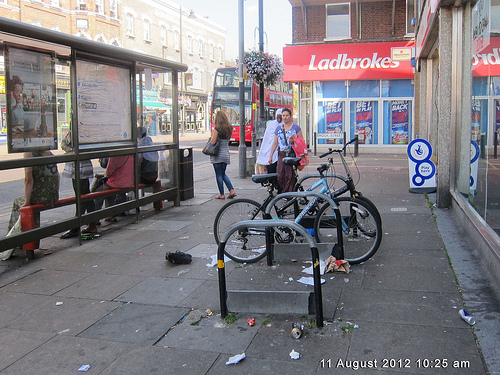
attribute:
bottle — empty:
[456, 307, 483, 335]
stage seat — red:
[18, 177, 164, 257]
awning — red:
[282, 39, 422, 92]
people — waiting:
[268, 106, 298, 180]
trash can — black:
[169, 142, 194, 200]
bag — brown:
[201, 133, 219, 158]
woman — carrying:
[271, 109, 311, 194]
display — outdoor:
[405, 139, 440, 192]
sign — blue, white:
[404, 133, 446, 205]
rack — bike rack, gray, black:
[212, 145, 380, 317]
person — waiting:
[138, 121, 158, 189]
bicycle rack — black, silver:
[217, 188, 354, 335]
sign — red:
[288, 35, 415, 88]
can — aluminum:
[288, 323, 304, 338]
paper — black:
[161, 250, 191, 266]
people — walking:
[192, 84, 349, 217]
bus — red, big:
[213, 66, 288, 152]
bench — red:
[13, 179, 161, 259]